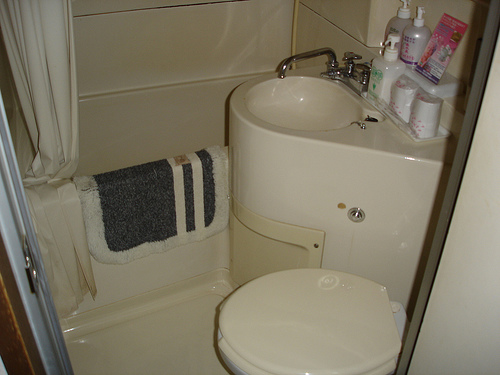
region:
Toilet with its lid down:
[212, 265, 407, 370]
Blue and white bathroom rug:
[70, 145, 225, 275]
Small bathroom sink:
[226, 41, 456, 166]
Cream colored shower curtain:
[0, 0, 96, 320]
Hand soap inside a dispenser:
[365, 30, 405, 110]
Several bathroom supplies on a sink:
[360, 0, 470, 145]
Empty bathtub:
[0, 0, 295, 340]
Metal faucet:
[271, 45, 367, 95]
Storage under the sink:
[227, 197, 322, 288]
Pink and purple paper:
[414, 10, 469, 87]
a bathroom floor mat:
[70, 143, 228, 259]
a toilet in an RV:
[212, 265, 405, 371]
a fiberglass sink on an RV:
[231, 45, 370, 137]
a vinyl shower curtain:
[0, 0, 80, 187]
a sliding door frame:
[1, 130, 71, 373]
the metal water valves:
[276, 46, 372, 93]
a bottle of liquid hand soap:
[367, 28, 405, 110]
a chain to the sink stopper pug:
[347, 119, 370, 131]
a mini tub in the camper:
[26, 72, 234, 196]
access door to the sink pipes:
[225, 208, 325, 285]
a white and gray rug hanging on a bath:
[73, 144, 235, 265]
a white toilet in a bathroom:
[213, 265, 403, 373]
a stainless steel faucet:
[276, 44, 372, 98]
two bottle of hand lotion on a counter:
[384, 0, 430, 71]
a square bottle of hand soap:
[366, 30, 403, 104]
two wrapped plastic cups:
[388, 75, 442, 139]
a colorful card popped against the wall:
[413, 10, 470, 87]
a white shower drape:
[0, 0, 82, 182]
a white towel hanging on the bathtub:
[25, 176, 97, 316]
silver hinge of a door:
[21, 238, 39, 295]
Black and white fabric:
[77, 152, 242, 264]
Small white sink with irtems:
[240, 30, 385, 173]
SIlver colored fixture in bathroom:
[339, 43, 358, 77]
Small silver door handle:
[18, 234, 51, 299]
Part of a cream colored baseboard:
[115, 291, 140, 312]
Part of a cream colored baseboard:
[136, 279, 193, 306]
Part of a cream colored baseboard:
[178, 263, 240, 292]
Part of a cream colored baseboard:
[56, 312, 102, 339]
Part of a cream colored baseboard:
[57, 265, 243, 299]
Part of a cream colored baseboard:
[90, 74, 212, 97]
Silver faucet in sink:
[262, 35, 370, 112]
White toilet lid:
[212, 249, 392, 374]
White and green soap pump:
[365, 30, 400, 105]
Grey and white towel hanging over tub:
[91, 141, 224, 251]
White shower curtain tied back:
[3, 1, 117, 296]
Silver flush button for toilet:
[342, 200, 364, 228]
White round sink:
[237, 64, 364, 161]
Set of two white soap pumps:
[383, 1, 433, 69]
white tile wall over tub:
[64, 0, 293, 100]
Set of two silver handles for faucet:
[342, 39, 374, 88]